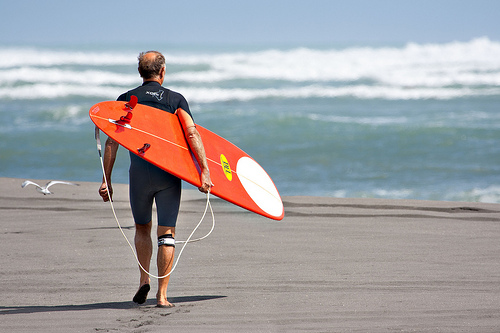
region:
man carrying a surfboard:
[48, 22, 280, 322]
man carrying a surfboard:
[79, 48, 259, 327]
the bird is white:
[13, 162, 80, 217]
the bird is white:
[12, 157, 83, 223]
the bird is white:
[13, 168, 82, 208]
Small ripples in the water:
[378, 164, 406, 194]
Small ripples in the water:
[423, 166, 448, 191]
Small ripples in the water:
[328, 86, 361, 114]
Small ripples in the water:
[385, 89, 417, 131]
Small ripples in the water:
[417, 91, 465, 133]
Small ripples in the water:
[18, 125, 59, 163]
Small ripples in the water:
[43, 96, 81, 129]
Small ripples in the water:
[221, 86, 263, 121]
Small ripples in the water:
[230, 105, 282, 153]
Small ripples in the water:
[269, 143, 308, 185]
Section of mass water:
[271, 79, 413, 157]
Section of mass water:
[313, 123, 498, 210]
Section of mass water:
[220, 64, 345, 158]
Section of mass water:
[1, 86, 81, 184]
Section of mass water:
[1, 42, 96, 112]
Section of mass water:
[175, 50, 337, 115]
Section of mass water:
[278, 91, 498, 178]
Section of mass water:
[386, 44, 498, 114]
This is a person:
[84, 46, 296, 316]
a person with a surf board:
[78, 41, 310, 331]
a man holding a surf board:
[87, 45, 285, 309]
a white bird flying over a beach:
[18, 173, 83, 203]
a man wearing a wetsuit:
[114, 70, 186, 234]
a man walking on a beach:
[83, 50, 181, 305]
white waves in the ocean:
[312, 40, 485, 97]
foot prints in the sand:
[121, 309, 191, 331]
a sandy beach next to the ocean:
[302, 198, 479, 331]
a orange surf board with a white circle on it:
[65, 97, 287, 222]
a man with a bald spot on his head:
[140, 46, 160, 67]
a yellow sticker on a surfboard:
[220, 155, 237, 177]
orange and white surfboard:
[93, 101, 284, 223]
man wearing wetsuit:
[93, 47, 224, 302]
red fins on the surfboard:
[110, 92, 150, 159]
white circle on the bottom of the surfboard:
[231, 157, 279, 217]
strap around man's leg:
[153, 235, 172, 247]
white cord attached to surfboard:
[80, 113, 226, 285]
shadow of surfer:
[5, 289, 222, 316]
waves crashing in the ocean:
[5, 43, 489, 200]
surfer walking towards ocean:
[62, 45, 293, 310]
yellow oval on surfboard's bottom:
[218, 154, 233, 184]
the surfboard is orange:
[88, 96, 314, 250]